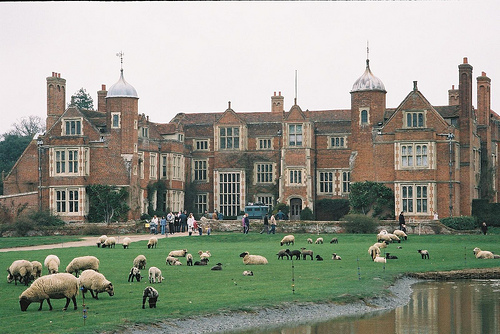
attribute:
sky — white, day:
[191, 15, 217, 25]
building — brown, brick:
[132, 120, 279, 187]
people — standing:
[150, 224, 248, 239]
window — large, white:
[219, 120, 234, 151]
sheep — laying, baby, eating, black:
[50, 272, 99, 292]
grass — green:
[218, 282, 266, 297]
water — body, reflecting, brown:
[432, 292, 465, 307]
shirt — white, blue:
[190, 218, 196, 222]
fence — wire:
[0, 213, 116, 228]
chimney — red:
[273, 96, 282, 115]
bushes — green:
[355, 182, 364, 195]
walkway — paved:
[77, 239, 91, 249]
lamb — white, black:
[235, 253, 263, 259]